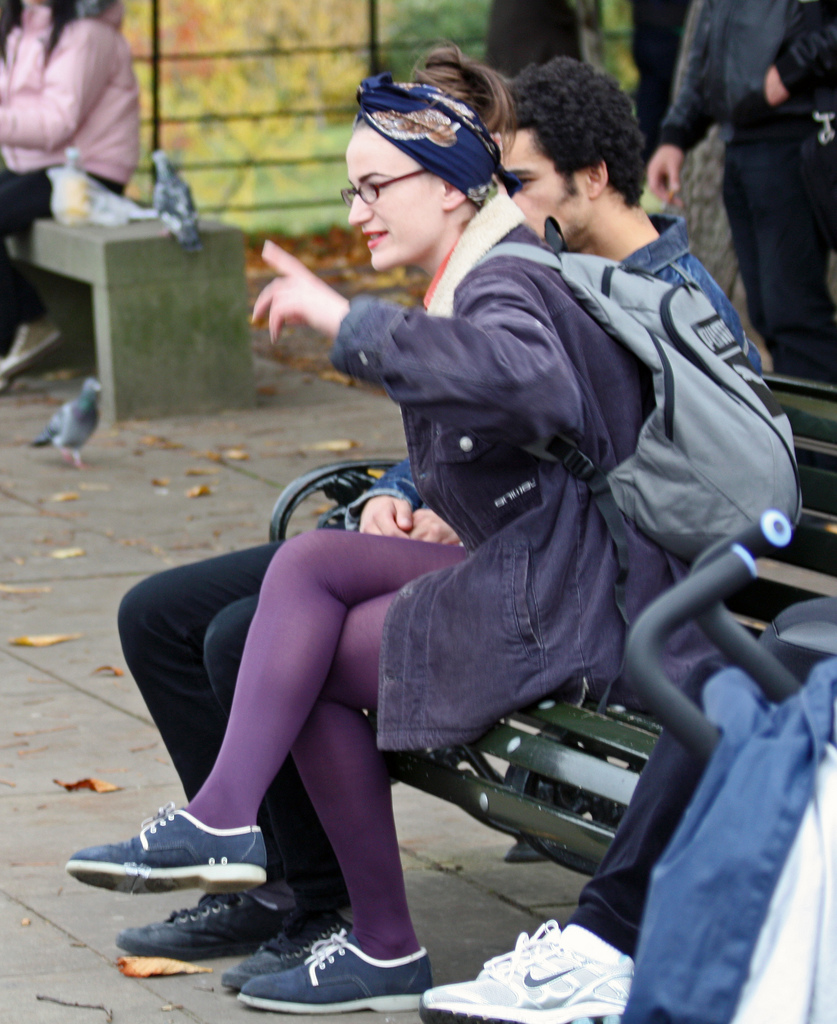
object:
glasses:
[340, 165, 429, 208]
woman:
[64, 46, 804, 1023]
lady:
[0, 0, 140, 392]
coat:
[0, 0, 140, 192]